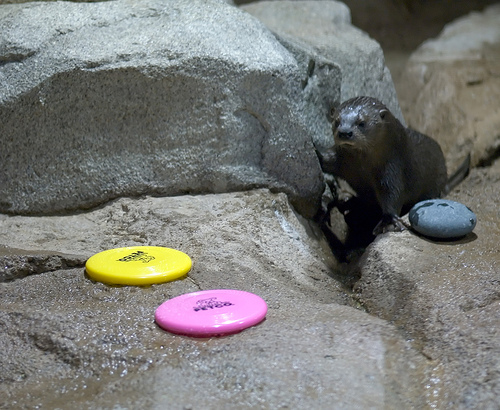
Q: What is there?
A: Meerkat.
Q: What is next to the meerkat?
A: Rock.